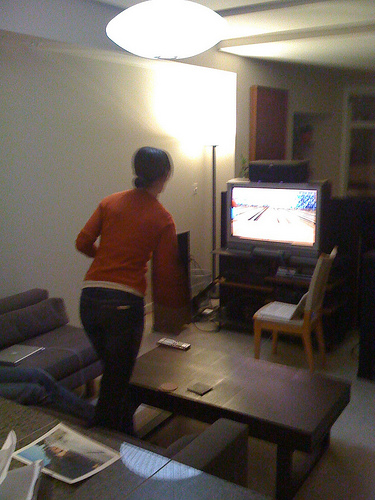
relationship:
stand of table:
[270, 447, 324, 499] [145, 323, 369, 460]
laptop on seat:
[264, 291, 307, 326] [253, 247, 339, 373]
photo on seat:
[33, 423, 119, 487] [260, 255, 326, 362]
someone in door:
[294, 118, 317, 176] [291, 112, 327, 185]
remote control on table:
[191, 383, 214, 399] [145, 323, 369, 460]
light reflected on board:
[180, 92, 243, 150] [7, 59, 225, 276]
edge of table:
[297, 368, 372, 466] [145, 323, 369, 460]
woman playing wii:
[110, 133, 185, 440] [276, 268, 299, 276]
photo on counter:
[10, 421, 122, 487] [5, 396, 280, 498]